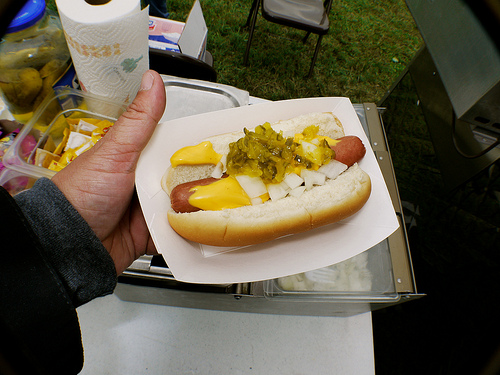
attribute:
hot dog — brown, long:
[171, 136, 365, 211]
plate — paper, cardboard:
[135, 97, 401, 286]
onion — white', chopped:
[235, 174, 268, 200]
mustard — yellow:
[170, 125, 343, 210]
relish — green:
[226, 122, 336, 186]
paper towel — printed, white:
[55, 2, 151, 115]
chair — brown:
[243, 0, 332, 78]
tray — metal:
[157, 71, 248, 126]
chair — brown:
[149, 46, 219, 82]